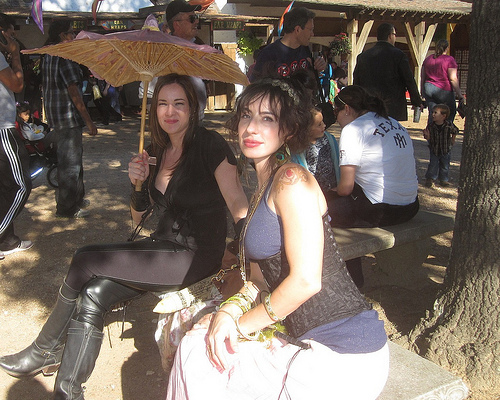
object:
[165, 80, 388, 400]
woman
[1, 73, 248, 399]
woman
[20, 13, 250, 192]
umbrella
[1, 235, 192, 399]
legs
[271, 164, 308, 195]
tattoo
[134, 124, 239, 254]
blouse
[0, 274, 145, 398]
boots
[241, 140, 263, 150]
lips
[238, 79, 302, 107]
headband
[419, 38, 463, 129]
woman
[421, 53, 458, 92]
shirt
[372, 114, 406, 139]
print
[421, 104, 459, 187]
boy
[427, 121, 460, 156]
shirt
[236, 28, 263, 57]
leaves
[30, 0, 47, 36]
flag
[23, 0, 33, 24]
pole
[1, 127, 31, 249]
pants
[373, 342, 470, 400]
bench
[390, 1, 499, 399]
tree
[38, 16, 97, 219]
man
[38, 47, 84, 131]
shirt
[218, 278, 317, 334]
forearms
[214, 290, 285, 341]
bracelets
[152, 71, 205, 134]
head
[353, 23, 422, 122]
man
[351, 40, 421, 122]
suit jacket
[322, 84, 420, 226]
woman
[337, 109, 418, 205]
shirt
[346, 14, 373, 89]
support post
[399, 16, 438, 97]
support post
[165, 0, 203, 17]
cap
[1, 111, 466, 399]
ground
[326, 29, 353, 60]
flowers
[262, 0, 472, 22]
awning